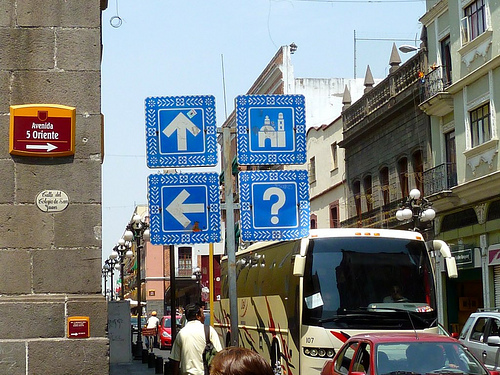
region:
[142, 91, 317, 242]
a bunch of blue signs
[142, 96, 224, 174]
a sign of an upwards arrow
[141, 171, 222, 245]
a sign of an arrow pointing left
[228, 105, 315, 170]
a sign of a small church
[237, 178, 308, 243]
a sign of a question mark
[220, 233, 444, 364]
a large white tour bus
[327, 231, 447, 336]
the front window of a bus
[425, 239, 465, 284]
the rear view mirror of a bus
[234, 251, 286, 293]
the side windows of a bus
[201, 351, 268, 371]
the brown hair of a person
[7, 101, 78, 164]
Orange and brown sign with an arrow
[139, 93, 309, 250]
four blue road signs with symbols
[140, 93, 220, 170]
Blue sign with arrow pointing up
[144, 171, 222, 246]
Blue sign with arrow pointing left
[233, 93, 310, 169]
Blue sign with picture of a building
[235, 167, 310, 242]
Blue sign with a question mark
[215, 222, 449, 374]
Big white bus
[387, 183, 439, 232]
Street lamp to the right of the bus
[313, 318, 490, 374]
Red car in front of the bus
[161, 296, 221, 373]
Man in a white shirt to the left of the bus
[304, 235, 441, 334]
the windshield of a bus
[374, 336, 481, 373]
the windshield of a car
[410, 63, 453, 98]
a person standing on a balcony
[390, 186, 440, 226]
the top of a lamp post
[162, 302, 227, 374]
a man walking down the street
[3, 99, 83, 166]
a street sign on a wall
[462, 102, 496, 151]
a window on a building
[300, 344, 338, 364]
the headlight of a bus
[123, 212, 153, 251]
the top of a lamp post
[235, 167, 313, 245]
a street sign with a question mark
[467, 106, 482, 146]
a window of a building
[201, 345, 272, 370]
part of a person's brown hair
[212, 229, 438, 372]
a large white bus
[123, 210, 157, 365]
part of a street light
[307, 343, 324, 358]
a headlight of a bus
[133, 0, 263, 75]
part of a blue sky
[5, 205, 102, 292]
part of a gray building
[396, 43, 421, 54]
a small security camera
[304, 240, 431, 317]
a large window of a bus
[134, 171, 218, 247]
the arrow is pointing left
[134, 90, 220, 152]
the arrow is pointing up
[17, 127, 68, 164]
the arrow is white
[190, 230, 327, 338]
the windows on the bus are black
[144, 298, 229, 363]
man is walking down the street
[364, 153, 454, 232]
the lights are off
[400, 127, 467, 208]
the terrace is empty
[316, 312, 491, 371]
the car is red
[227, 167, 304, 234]
a question mark on the sign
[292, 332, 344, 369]
the headlight is off